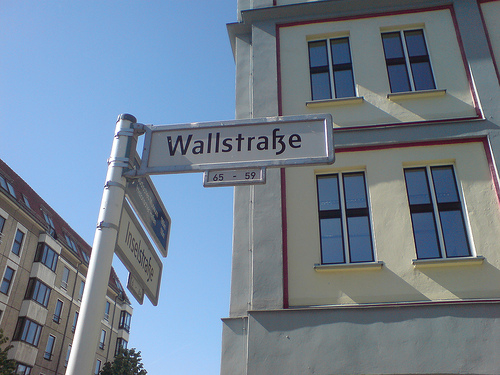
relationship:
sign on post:
[139, 113, 335, 187] [74, 116, 135, 370]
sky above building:
[1, 15, 232, 373] [219, 0, 500, 375]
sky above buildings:
[1, 15, 232, 373] [1, 128, 135, 373]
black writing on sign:
[166, 128, 300, 156] [148, 109, 338, 163]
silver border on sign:
[138, 113, 336, 177] [137, 111, 339, 176]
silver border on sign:
[138, 113, 336, 177] [124, 157, 172, 257]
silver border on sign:
[138, 113, 336, 177] [114, 150, 171, 305]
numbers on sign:
[210, 167, 259, 182] [197, 163, 279, 191]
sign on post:
[135, 113, 335, 184] [58, 111, 135, 373]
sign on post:
[114, 150, 171, 305] [58, 111, 135, 373]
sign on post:
[114, 150, 171, 305] [76, 122, 138, 353]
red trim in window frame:
[276, 0, 500, 130] [290, 25, 395, 132]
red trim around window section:
[277, 135, 499, 315] [309, 165, 484, 280]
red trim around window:
[449, 5, 489, 120] [299, 25, 364, 105]